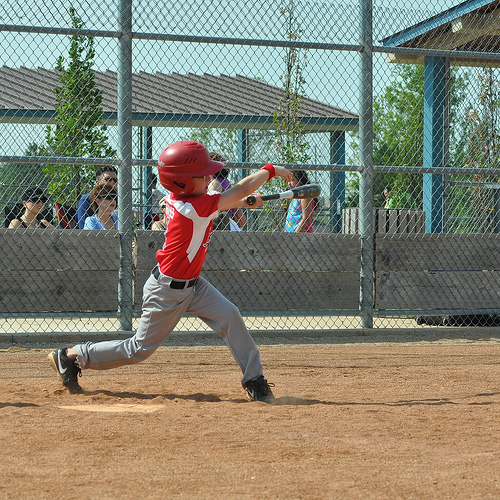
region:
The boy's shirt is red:
[144, 197, 219, 277]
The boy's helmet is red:
[147, 119, 231, 199]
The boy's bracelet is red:
[250, 153, 287, 175]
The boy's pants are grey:
[69, 290, 264, 373]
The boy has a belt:
[130, 261, 230, 301]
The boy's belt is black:
[134, 262, 250, 305]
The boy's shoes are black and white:
[42, 340, 107, 405]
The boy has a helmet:
[145, 122, 215, 192]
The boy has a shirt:
[140, 175, 230, 280]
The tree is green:
[35, 60, 116, 212]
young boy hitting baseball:
[48, 137, 326, 404]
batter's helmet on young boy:
[159, 137, 226, 199]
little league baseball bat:
[236, 178, 328, 213]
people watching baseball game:
[12, 163, 127, 230]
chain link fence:
[8, 1, 498, 328]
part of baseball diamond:
[6, 343, 498, 498]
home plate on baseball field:
[50, 392, 168, 419]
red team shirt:
[152, 189, 226, 289]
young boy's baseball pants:
[81, 262, 266, 382]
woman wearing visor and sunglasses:
[81, 182, 122, 230]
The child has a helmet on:
[121, 133, 248, 211]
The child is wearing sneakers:
[24, 330, 322, 433]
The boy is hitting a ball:
[113, 127, 371, 237]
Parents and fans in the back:
[15, 186, 410, 266]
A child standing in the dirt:
[36, 363, 318, 465]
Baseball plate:
[43, 388, 178, 460]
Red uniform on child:
[130, 192, 252, 284]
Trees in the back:
[38, 17, 405, 144]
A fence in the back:
[18, 198, 425, 344]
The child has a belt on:
[133, 255, 233, 334]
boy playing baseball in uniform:
[101, 124, 335, 486]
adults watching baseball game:
[14, 157, 133, 265]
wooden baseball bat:
[235, 176, 347, 229]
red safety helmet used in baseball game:
[141, 142, 256, 206]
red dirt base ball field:
[205, 323, 489, 487]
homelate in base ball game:
[40, 363, 192, 464]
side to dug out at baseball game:
[367, 1, 492, 350]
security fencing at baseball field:
[25, 7, 477, 444]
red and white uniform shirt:
[148, 181, 239, 312]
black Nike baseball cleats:
[40, 331, 89, 403]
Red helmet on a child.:
[155, 138, 225, 189]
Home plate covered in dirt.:
[52, 399, 166, 417]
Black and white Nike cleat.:
[237, 376, 279, 403]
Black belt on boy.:
[150, 267, 201, 290]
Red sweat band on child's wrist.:
[260, 162, 275, 178]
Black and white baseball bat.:
[245, 179, 323, 205]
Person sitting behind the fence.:
[8, 187, 56, 230]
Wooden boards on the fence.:
[131, 226, 365, 316]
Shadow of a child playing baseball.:
[80, 385, 498, 405]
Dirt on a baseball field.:
[79, 425, 149, 462]